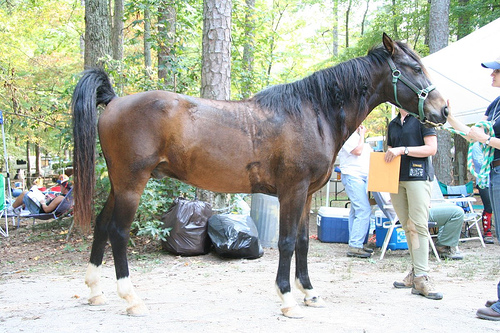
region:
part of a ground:
[203, 253, 233, 278]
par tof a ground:
[201, 254, 228, 284]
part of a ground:
[200, 274, 239, 319]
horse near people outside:
[58, 28, 450, 308]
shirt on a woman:
[371, 113, 447, 186]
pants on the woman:
[372, 181, 435, 269]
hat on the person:
[475, 48, 499, 71]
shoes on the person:
[473, 295, 498, 317]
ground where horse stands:
[10, 260, 471, 325]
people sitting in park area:
[17, 158, 74, 225]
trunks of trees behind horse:
[48, 28, 271, 233]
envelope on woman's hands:
[364, 148, 411, 196]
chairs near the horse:
[379, 173, 488, 263]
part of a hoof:
[264, 307, 306, 317]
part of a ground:
[152, 293, 184, 313]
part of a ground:
[180, 266, 244, 296]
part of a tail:
[59, 165, 117, 213]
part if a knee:
[262, 235, 292, 270]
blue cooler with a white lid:
[317, 205, 370, 244]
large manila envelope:
[366, 150, 400, 192]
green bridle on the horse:
[380, 50, 435, 122]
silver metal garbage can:
[250, 193, 279, 247]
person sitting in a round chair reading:
[8, 179, 73, 219]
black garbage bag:
[207, 212, 262, 257]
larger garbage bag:
[160, 195, 212, 252]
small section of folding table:
[329, 177, 349, 206]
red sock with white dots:
[481, 210, 491, 235]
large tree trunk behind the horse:
[200, 1, 232, 211]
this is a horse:
[75, 43, 468, 316]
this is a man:
[381, 113, 442, 295]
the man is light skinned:
[410, 139, 437, 155]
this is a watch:
[402, 143, 410, 160]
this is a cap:
[471, 57, 498, 67]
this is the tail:
[66, 73, 96, 198]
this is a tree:
[128, 0, 195, 82]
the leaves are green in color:
[167, 33, 189, 64]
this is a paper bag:
[212, 213, 257, 258]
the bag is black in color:
[223, 216, 243, 243]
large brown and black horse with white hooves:
[62, 30, 449, 320]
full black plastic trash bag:
[202, 200, 267, 264]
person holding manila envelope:
[363, 98, 450, 303]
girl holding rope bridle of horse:
[441, 48, 497, 329]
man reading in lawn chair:
[4, 174, 74, 232]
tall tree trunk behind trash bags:
[191, 1, 233, 207]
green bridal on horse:
[372, 32, 450, 125]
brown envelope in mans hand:
[364, 151, 402, 196]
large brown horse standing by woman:
[57, 32, 453, 329]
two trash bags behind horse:
[163, 197, 265, 262]